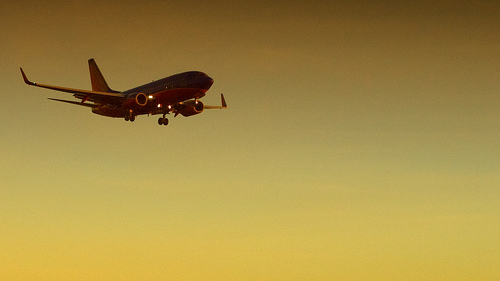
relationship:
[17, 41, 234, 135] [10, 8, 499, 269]
airplane in sky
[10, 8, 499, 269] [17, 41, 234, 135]
sky with airplane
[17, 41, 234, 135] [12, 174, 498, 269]
plane flying into sunset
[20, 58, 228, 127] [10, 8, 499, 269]
airplane in sky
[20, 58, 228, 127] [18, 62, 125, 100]
airplane has wing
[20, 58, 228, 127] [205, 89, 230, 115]
airplane has wing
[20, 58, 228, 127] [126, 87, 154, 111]
airplane has jet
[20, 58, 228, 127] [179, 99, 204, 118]
airplane has jet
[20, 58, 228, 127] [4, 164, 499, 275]
airplane before landing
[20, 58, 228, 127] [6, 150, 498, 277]
airplane flying to land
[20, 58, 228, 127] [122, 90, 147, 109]
airplane has engine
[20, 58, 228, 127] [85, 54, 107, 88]
airplane has tail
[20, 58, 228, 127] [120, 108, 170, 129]
airplane has wheels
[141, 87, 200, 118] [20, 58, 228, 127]
lights on airplane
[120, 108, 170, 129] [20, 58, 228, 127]
wheels under airplane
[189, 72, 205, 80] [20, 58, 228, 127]
windshield front of airplane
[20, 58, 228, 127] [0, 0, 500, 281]
airplane in sky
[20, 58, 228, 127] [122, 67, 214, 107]
airplane has body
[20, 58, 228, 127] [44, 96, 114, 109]
airplane has flap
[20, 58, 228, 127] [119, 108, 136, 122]
airplane has tires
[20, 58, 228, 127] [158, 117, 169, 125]
airplane has wheels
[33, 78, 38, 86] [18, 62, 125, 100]
light on wing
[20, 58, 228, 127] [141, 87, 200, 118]
airplane has lights